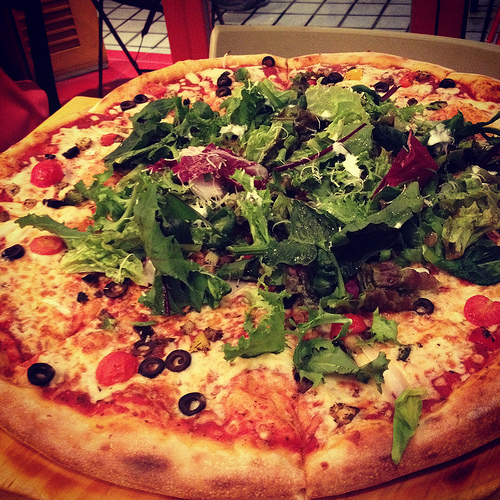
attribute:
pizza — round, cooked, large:
[0, 50, 499, 499]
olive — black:
[261, 56, 275, 68]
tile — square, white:
[283, 2, 320, 15]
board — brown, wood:
[1, 97, 498, 497]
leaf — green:
[306, 85, 364, 119]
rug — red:
[0, 45, 174, 153]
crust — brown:
[1, 50, 498, 499]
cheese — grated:
[2, 65, 497, 448]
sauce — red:
[0, 63, 497, 457]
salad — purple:
[145, 144, 270, 193]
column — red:
[162, 2, 215, 62]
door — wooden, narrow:
[6, 2, 110, 84]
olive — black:
[374, 81, 389, 93]